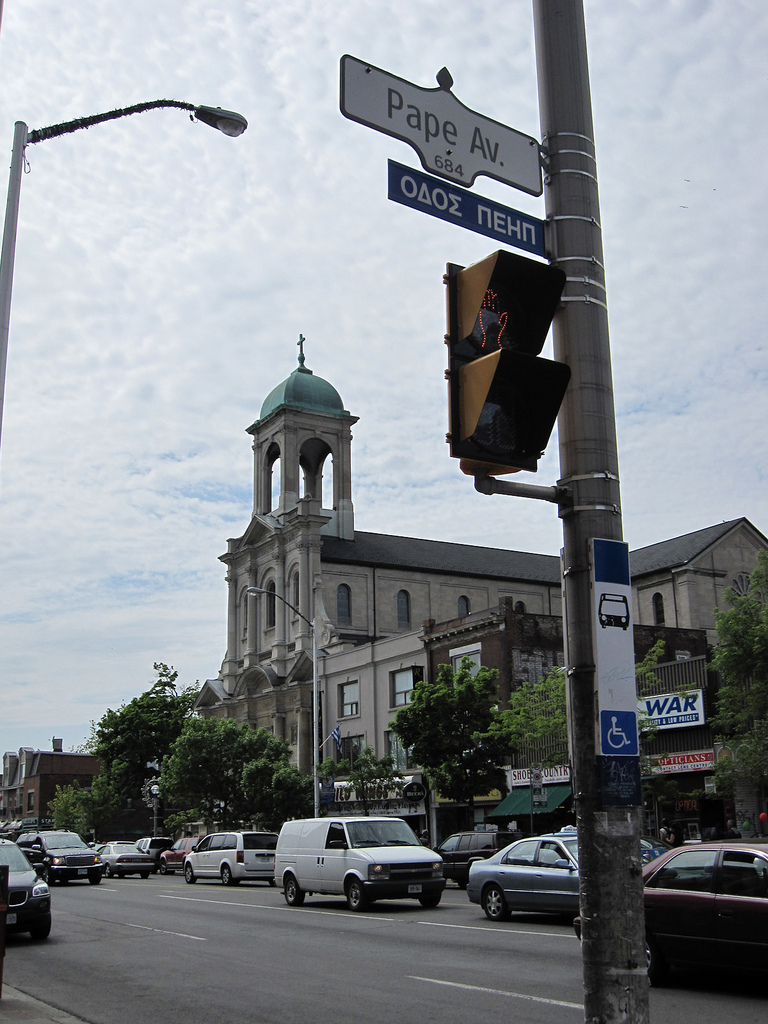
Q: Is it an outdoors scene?
A: Yes, it is outdoors.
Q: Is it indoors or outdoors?
A: It is outdoors.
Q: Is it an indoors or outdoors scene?
A: It is outdoors.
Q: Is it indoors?
A: No, it is outdoors.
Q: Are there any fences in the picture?
A: No, there are no fences.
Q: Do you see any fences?
A: No, there are no fences.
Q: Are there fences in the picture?
A: No, there are no fences.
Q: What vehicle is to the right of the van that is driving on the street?
A: The vehicle is a car.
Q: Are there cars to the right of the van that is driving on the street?
A: Yes, there is a car to the right of the van.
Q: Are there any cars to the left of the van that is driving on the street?
A: No, the car is to the right of the van.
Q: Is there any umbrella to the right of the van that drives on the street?
A: No, there is a car to the right of the van.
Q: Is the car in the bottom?
A: Yes, the car is in the bottom of the image.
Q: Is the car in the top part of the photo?
A: No, the car is in the bottom of the image.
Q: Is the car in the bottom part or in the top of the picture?
A: The car is in the bottom of the image.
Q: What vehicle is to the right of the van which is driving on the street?
A: The vehicle is a car.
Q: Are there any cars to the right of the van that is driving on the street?
A: Yes, there is a car to the right of the van.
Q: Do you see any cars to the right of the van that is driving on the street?
A: Yes, there is a car to the right of the van.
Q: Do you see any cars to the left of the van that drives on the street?
A: No, the car is to the right of the van.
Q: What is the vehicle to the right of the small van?
A: The vehicle is a car.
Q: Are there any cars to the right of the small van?
A: Yes, there is a car to the right of the van.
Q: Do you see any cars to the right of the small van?
A: Yes, there is a car to the right of the van.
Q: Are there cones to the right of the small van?
A: No, there is a car to the right of the van.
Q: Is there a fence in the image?
A: No, there are no fences.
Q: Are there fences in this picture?
A: No, there are no fences.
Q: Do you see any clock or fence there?
A: No, there are no fences or clocks.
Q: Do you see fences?
A: No, there are no fences.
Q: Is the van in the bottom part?
A: Yes, the van is in the bottom of the image.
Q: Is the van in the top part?
A: No, the van is in the bottom of the image.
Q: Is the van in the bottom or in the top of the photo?
A: The van is in the bottom of the image.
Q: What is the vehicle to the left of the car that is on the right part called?
A: The vehicle is a van.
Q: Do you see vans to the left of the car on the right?
A: Yes, there is a van to the left of the car.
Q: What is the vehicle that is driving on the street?
A: The vehicle is a van.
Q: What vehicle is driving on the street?
A: The vehicle is a van.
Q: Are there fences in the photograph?
A: No, there are no fences.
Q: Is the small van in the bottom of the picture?
A: Yes, the van is in the bottom of the image.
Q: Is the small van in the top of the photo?
A: No, the van is in the bottom of the image.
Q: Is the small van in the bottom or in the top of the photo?
A: The van is in the bottom of the image.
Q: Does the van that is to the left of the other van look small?
A: Yes, the van is small.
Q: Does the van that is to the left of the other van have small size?
A: Yes, the van is small.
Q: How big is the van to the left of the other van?
A: The van is small.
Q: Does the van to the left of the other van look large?
A: No, the van is small.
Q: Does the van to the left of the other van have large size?
A: No, the van is small.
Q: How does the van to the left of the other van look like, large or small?
A: The van is small.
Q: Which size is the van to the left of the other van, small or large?
A: The van is small.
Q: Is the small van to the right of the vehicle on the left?
A: Yes, the van is to the right of the vehicle.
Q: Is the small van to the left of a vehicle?
A: No, the van is to the right of a vehicle.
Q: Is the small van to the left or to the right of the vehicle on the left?
A: The van is to the right of the vehicle.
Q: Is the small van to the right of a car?
A: No, the van is to the left of a car.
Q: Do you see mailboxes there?
A: No, there are no mailboxes.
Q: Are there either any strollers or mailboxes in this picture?
A: No, there are no mailboxes or strollers.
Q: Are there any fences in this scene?
A: No, there are no fences.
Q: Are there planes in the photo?
A: No, there are no planes.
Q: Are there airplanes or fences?
A: No, there are no airplanes or fences.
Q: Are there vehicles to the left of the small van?
A: Yes, there is a vehicle to the left of the van.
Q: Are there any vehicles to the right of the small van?
A: No, the vehicle is to the left of the van.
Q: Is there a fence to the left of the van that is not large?
A: No, there is a vehicle to the left of the van.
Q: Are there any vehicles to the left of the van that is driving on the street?
A: Yes, there is a vehicle to the left of the van.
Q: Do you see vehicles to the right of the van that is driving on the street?
A: No, the vehicle is to the left of the van.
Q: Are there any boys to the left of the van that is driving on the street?
A: No, there is a vehicle to the left of the van.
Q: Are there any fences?
A: No, there are no fences.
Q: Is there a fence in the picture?
A: No, there are no fences.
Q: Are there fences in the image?
A: No, there are no fences.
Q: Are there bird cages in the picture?
A: No, there are no bird cages.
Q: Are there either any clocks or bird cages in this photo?
A: No, there are no bird cages or clocks.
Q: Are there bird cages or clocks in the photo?
A: No, there are no bird cages or clocks.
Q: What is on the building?
A: The dome is on the building.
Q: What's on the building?
A: The dome is on the building.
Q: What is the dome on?
A: The dome is on the building.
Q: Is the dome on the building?
A: Yes, the dome is on the building.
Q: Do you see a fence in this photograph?
A: No, there are no fences.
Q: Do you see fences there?
A: No, there are no fences.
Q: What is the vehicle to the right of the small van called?
A: The vehicle is a car.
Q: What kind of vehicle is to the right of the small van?
A: The vehicle is a car.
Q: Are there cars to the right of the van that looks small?
A: Yes, there is a car to the right of the van.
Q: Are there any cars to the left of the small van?
A: No, the car is to the right of the van.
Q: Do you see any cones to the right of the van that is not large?
A: No, there is a car to the right of the van.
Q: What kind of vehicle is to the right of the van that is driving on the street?
A: The vehicle is a car.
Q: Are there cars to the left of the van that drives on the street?
A: No, the car is to the right of the van.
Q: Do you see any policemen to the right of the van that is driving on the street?
A: No, there is a car to the right of the van.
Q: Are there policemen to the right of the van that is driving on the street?
A: No, there is a car to the right of the van.